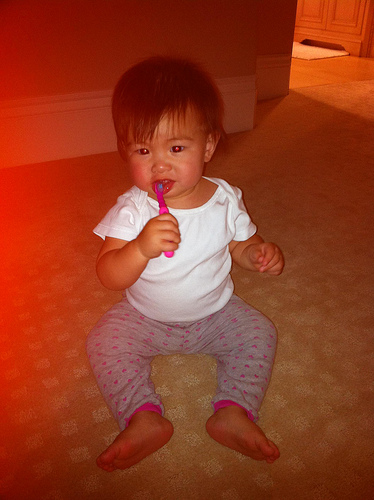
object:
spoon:
[154, 180, 174, 257]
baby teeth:
[164, 179, 170, 184]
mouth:
[149, 177, 176, 196]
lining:
[212, 398, 254, 420]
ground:
[301, 87, 312, 115]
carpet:
[0, 80, 372, 498]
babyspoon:
[153, 181, 175, 258]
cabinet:
[293, 1, 372, 58]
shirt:
[93, 175, 258, 325]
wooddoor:
[325, 0, 365, 35]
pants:
[87, 292, 277, 431]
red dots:
[112, 344, 119, 349]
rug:
[291, 39, 350, 61]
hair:
[111, 53, 228, 161]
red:
[175, 145, 180, 153]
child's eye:
[169, 144, 187, 153]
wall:
[2, 0, 297, 169]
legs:
[85, 295, 163, 419]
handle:
[159, 205, 175, 257]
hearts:
[251, 343, 257, 348]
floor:
[0, 56, 373, 498]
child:
[84, 55, 284, 473]